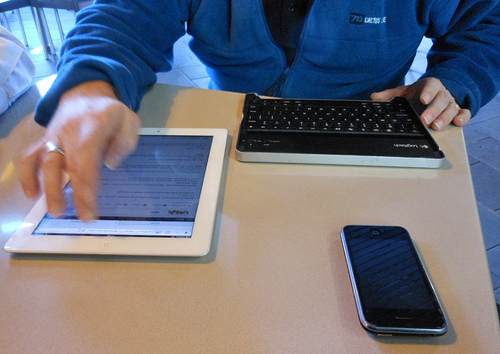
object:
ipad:
[1, 125, 229, 260]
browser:
[31, 134, 217, 237]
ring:
[41, 140, 66, 156]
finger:
[39, 134, 68, 218]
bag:
[0, 25, 37, 115]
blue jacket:
[34, 1, 499, 124]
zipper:
[256, 0, 319, 94]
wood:
[410, 179, 467, 242]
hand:
[16, 80, 141, 222]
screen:
[24, 134, 215, 238]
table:
[0, 70, 499, 352]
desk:
[0, 70, 500, 354]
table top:
[0, 72, 500, 352]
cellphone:
[338, 223, 450, 338]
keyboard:
[235, 91, 443, 169]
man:
[9, 0, 500, 226]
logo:
[350, 13, 387, 24]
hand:
[369, 76, 471, 128]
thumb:
[370, 85, 405, 101]